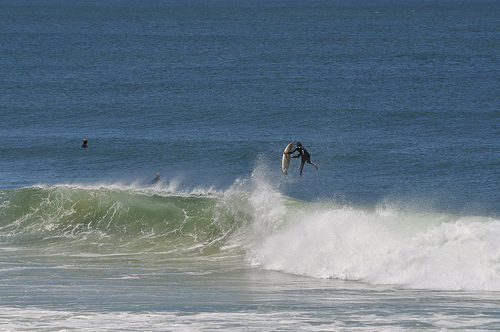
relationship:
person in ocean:
[288, 127, 314, 172] [131, 17, 256, 103]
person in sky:
[288, 127, 314, 172] [332, 28, 365, 74]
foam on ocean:
[156, 202, 213, 253] [131, 17, 256, 103]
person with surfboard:
[288, 127, 314, 172] [276, 129, 296, 171]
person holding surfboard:
[288, 127, 314, 172] [276, 129, 296, 171]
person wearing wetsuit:
[288, 127, 314, 172] [281, 139, 319, 159]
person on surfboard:
[288, 127, 314, 172] [276, 129, 296, 171]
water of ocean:
[182, 0, 200, 9] [131, 17, 256, 103]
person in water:
[288, 127, 314, 172] [182, 0, 200, 9]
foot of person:
[308, 162, 318, 172] [288, 127, 314, 172]